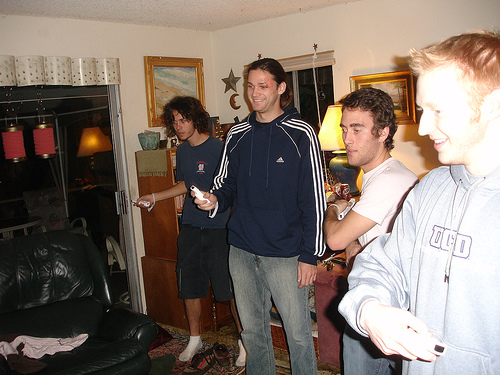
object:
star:
[219, 69, 242, 94]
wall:
[208, 1, 499, 178]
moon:
[227, 93, 241, 110]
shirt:
[174, 138, 231, 230]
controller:
[190, 184, 210, 202]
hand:
[190, 189, 218, 212]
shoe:
[191, 344, 225, 372]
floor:
[146, 313, 343, 373]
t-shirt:
[352, 157, 421, 245]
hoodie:
[209, 111, 329, 268]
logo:
[276, 155, 285, 163]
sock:
[179, 335, 203, 363]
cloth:
[1, 328, 92, 362]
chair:
[1, 228, 159, 373]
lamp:
[77, 127, 113, 186]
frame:
[142, 54, 208, 130]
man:
[190, 58, 330, 374]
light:
[317, 104, 360, 197]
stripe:
[286, 120, 329, 260]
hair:
[247, 57, 294, 110]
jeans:
[228, 244, 320, 374]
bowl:
[137, 129, 161, 151]